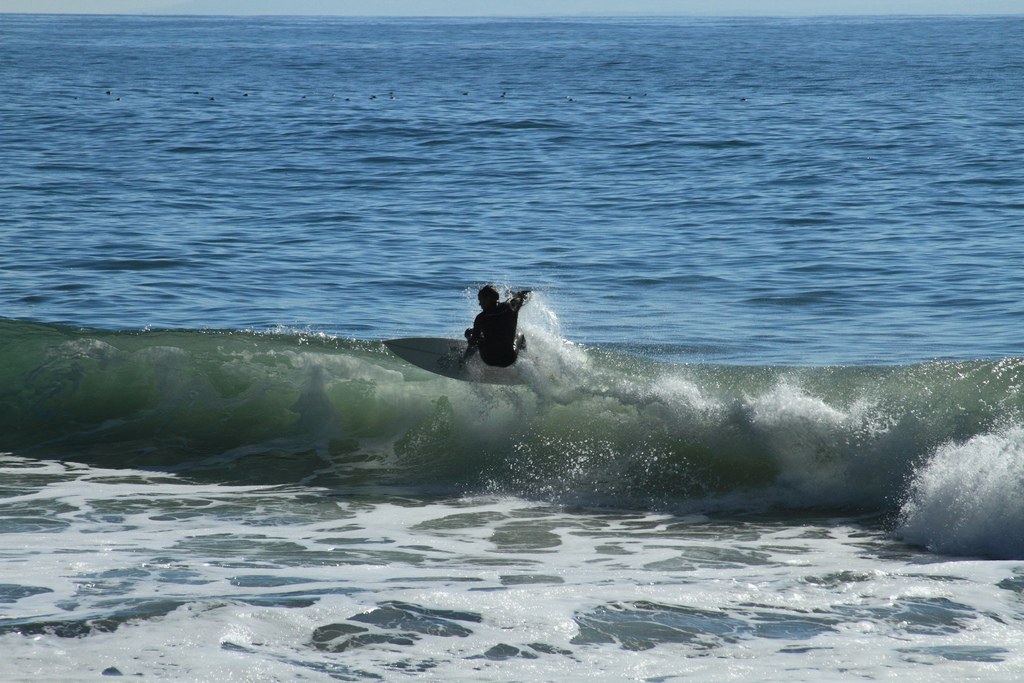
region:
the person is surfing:
[352, 254, 654, 471]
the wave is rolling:
[623, 263, 979, 615]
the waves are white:
[127, 282, 1004, 649]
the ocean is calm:
[209, 2, 950, 317]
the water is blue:
[370, 0, 925, 305]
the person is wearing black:
[323, 272, 577, 391]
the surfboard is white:
[324, 315, 560, 421]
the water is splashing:
[829, 370, 1010, 592]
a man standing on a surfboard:
[457, 279, 533, 365]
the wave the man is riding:
[5, 313, 1023, 541]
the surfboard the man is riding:
[381, 332, 524, 393]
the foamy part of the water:
[3, 449, 1022, 675]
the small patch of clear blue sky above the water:
[0, 2, 1023, 22]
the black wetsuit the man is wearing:
[455, 300, 526, 368]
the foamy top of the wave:
[572, 366, 1022, 550]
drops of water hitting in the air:
[498, 427, 683, 501]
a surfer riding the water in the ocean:
[379, 281, 542, 381]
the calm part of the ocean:
[24, 19, 1001, 334]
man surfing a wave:
[456, 260, 545, 369]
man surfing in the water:
[458, 279, 534, 375]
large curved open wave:
[0, 318, 1022, 541]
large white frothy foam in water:
[902, 423, 1020, 566]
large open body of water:
[1, 17, 1023, 366]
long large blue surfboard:
[385, 331, 554, 389]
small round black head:
[478, 283, 502, 310]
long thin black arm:
[456, 309, 486, 361]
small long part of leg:
[516, 324, 530, 357]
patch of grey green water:
[577, 594, 831, 649]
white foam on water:
[0, 532, 165, 575]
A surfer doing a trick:
[380, 277, 628, 421]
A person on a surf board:
[383, 252, 596, 414]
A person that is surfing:
[380, 271, 634, 401]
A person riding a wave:
[354, 277, 612, 405]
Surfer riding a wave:
[374, 273, 613, 407]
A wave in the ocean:
[29, 306, 997, 542]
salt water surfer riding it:
[50, 299, 961, 562]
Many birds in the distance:
[93, 63, 909, 172]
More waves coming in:
[96, 69, 890, 295]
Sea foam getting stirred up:
[61, 461, 862, 651]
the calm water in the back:
[12, 14, 1021, 354]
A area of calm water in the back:
[11, 4, 1020, 377]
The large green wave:
[11, 310, 1020, 536]